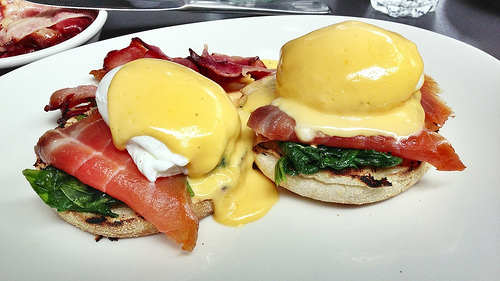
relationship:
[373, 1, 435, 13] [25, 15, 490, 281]
glass near plate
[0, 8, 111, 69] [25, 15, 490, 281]
dish behind plate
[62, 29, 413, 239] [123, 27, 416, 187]
sandwich has sauce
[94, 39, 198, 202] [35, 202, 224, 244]
food on muffin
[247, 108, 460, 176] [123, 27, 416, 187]
fish under sauce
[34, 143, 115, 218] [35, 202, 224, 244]
spinach on muffin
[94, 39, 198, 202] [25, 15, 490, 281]
food on plate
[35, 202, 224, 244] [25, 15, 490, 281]
muffin on plate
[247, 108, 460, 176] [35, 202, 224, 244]
fish on muffin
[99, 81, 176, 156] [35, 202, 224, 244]
egg on muffin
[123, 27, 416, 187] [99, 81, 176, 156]
sauce on egg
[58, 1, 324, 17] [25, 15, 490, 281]
knife behind plate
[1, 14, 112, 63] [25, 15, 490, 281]
dish near plate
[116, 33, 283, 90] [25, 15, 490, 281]
bacon on plate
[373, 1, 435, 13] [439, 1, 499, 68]
glass on table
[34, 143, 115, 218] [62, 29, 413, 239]
spinach on sandwich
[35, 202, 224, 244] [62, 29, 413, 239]
muffin beneath sandwich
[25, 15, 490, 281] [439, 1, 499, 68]
plate on table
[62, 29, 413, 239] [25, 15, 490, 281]
sandwich sitting on plate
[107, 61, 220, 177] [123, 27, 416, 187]
eggs under sauce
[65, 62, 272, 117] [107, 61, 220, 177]
ham under eggs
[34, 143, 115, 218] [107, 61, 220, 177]
spinach under eggs